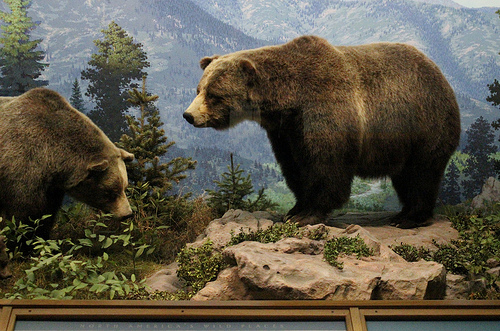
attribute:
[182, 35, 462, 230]
bear — foraging, grizzly, in woods, big, brown, on right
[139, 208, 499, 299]
rock — big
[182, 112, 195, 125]
nose — black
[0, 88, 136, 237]
bear — brown, on left, foraging, grizzly, in woods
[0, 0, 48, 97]
tree — pine, in back, green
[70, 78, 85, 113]
tree — pine, green, in back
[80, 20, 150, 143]
tree — in back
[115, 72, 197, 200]
tree — green, pine, young, in back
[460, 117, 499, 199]
tree — in back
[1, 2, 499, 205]
mountains — in background, tall, grassy, foggy looking, in back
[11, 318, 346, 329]
placard — for exhibit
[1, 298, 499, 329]
frame — wooden